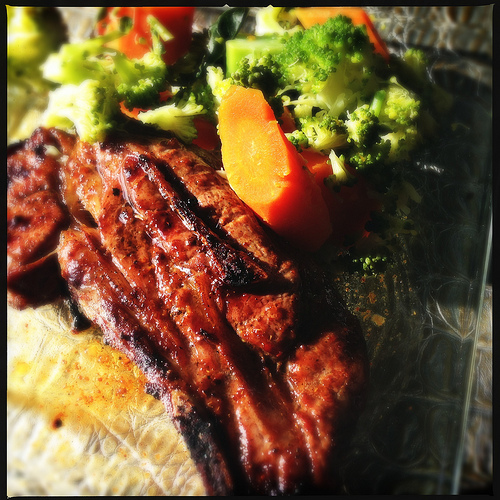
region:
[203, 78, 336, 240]
orange carrots on meat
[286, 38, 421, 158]
green broccoli on plate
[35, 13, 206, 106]
green pieces of broccoli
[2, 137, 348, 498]
slices of meat on trey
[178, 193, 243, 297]
black burnt part of meat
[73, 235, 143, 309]
red color on meat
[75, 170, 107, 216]
tan color on meat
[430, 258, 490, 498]
white line on surface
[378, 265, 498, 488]
silver background of food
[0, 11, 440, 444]
meat and vegetables on trey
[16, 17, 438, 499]
a delicious meal ready to be eaten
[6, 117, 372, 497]
this looks like seared chicken breast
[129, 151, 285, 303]
the diner will need to be careful of chicken bones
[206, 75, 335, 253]
this looks like sweet potato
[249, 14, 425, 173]
broccoli is part of this meal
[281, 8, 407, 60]
chopped carrots are part of this meal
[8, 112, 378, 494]
the chicken looks pretty juicy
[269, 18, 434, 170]
the dark green of the broccoli indicates lots of healthy nutrients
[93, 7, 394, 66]
the dark orange of the carrots indicates healthy nutrients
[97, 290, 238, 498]
the meat has been seared black in places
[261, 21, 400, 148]
broccoli on the plate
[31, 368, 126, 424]
bread on the plate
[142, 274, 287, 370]
meat on the plate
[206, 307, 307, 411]
sauce on the meat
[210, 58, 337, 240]
carrot on the plate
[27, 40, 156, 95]
broccoli on the plate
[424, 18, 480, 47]
the plate is blurry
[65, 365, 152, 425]
sauce on the bread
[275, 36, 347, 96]
head of the broccoli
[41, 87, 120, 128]
tail of the broccoli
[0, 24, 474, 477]
food on a plate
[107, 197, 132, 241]
red color on meat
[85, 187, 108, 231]
tan color on meat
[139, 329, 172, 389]
black color on meat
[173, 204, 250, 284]
burnt spots on meat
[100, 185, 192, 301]
rough texture to meat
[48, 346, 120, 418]
greasy orange stain on surface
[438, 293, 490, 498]
long white line down surface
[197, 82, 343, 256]
slice of a carrot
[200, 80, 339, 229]
orange piece of carrot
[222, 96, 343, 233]
orange slice of a carrot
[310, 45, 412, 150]
green piece of broccoli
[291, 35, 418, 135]
green broccoli floret piece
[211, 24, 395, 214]
carrot and broccoli together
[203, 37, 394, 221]
orange carrot and green broccoli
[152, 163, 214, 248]
black burnt side of meat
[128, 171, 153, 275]
red color on meat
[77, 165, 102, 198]
tan color on meat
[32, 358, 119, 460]
orange greasy color on surface